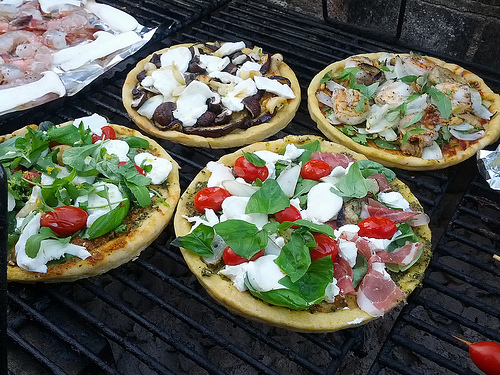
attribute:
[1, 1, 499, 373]
grill — metal, black, dirty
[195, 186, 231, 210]
tomato — red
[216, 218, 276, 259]
basil — green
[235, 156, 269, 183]
tomato — red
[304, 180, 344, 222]
mozzarella cheese — white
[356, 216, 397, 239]
tomato — red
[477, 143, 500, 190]
foil — crumpled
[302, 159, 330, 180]
tomato — red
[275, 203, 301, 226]
tomato — red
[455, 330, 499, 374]
vegetable — red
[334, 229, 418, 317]
meat — red